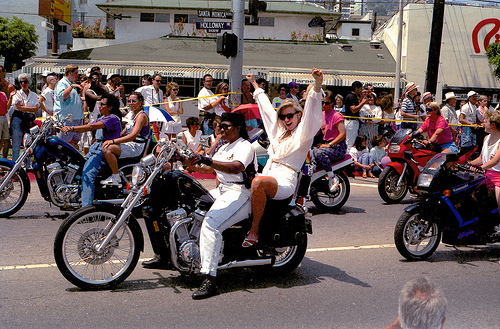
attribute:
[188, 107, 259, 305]
driver — white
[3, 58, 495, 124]
people — watching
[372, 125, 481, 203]
motorcycle — red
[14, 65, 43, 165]
man — watching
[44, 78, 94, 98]
arms — up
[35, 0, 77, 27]
sign — yellow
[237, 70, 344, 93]
hands — up